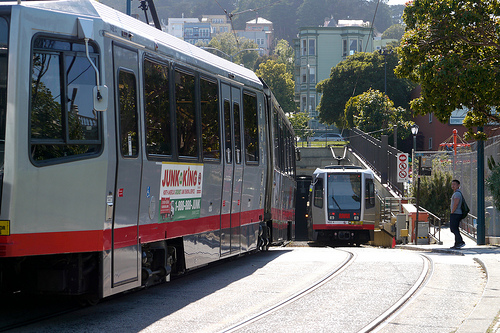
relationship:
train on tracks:
[306, 160, 383, 248] [185, 239, 434, 332]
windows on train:
[239, 87, 270, 168] [2, 0, 305, 325]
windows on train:
[199, 77, 227, 163] [2, 0, 305, 325]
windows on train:
[171, 65, 204, 154] [2, 0, 305, 325]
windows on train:
[135, 52, 177, 159] [2, 0, 305, 325]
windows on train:
[111, 68, 148, 152] [2, 0, 305, 325]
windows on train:
[23, 30, 109, 171] [2, 0, 305, 325]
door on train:
[102, 35, 153, 295] [2, 0, 305, 325]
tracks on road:
[185, 239, 434, 332] [37, 232, 490, 331]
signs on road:
[389, 148, 413, 208] [37, 232, 490, 331]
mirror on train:
[92, 83, 110, 115] [2, 0, 305, 325]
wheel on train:
[319, 229, 374, 249] [306, 160, 383, 248]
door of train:
[102, 35, 153, 295] [2, 0, 305, 325]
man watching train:
[444, 176, 470, 251] [2, 0, 305, 325]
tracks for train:
[185, 239, 434, 332] [306, 160, 383, 248]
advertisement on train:
[153, 162, 207, 221] [2, 0, 305, 325]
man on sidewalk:
[444, 176, 470, 251] [428, 221, 500, 332]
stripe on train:
[312, 220, 378, 235] [306, 160, 383, 248]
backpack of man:
[459, 197, 471, 221] [444, 176, 470, 251]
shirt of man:
[448, 191, 466, 216] [444, 176, 470, 251]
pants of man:
[448, 211, 470, 246] [444, 176, 470, 251]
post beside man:
[410, 155, 433, 244] [444, 176, 470, 251]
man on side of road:
[444, 176, 470, 251] [37, 232, 490, 331]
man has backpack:
[444, 176, 470, 251] [459, 197, 471, 221]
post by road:
[410, 155, 433, 244] [37, 232, 490, 331]